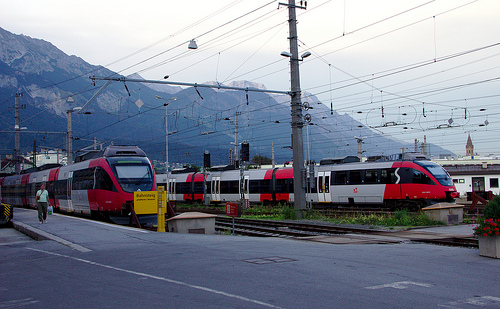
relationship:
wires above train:
[12, 1, 494, 170] [156, 156, 461, 210]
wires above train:
[12, 1, 494, 170] [0, 148, 164, 213]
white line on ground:
[23, 244, 280, 307] [0, 208, 494, 304]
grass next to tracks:
[335, 197, 374, 222] [156, 201, 477, 253]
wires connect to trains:
[201, 2, 498, 57] [1, 145, 169, 214]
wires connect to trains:
[305, 87, 497, 116] [1, 145, 169, 214]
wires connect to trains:
[311, 116, 498, 131] [1, 145, 169, 214]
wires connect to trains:
[76, 107, 289, 132] [1, 145, 169, 214]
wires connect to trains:
[311, 65, 498, 75] [1, 145, 169, 214]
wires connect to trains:
[201, 2, 498, 57] [158, 160, 459, 206]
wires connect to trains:
[305, 87, 497, 116] [158, 160, 459, 206]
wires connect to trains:
[311, 116, 498, 131] [158, 160, 459, 206]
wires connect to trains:
[76, 107, 289, 132] [158, 160, 459, 206]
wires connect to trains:
[311, 65, 498, 75] [158, 160, 459, 206]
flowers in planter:
[475, 214, 498, 234] [402, 197, 459, 241]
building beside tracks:
[443, 153, 498, 197] [242, 212, 343, 237]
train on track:
[0, 145, 155, 228] [134, 210, 499, 246]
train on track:
[155, 157, 460, 203] [306, 203, 426, 214]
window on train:
[113, 162, 150, 180] [1, 155, 158, 221]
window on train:
[424, 163, 449, 178] [156, 156, 461, 210]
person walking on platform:
[35, 184, 50, 225] [11, 202, 156, 249]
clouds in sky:
[80, 7, 380, 67] [2, 8, 497, 166]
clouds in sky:
[361, 13, 462, 80] [333, 12, 472, 97]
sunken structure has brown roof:
[165, 209, 219, 234] [162, 207, 221, 221]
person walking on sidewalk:
[29, 184, 81, 231] [14, 196, 155, 246]